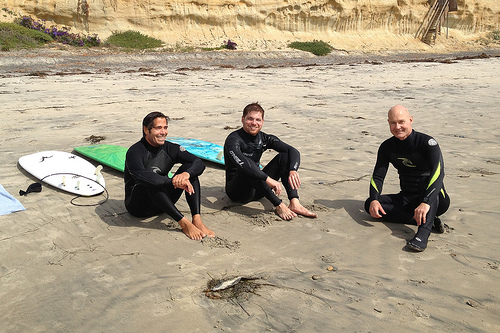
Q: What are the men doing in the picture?
A: Sitting.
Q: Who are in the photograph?
A: Men.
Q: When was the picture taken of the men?
A: Daytime.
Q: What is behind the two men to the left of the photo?
A: Surfboards.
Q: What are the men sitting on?
A: Sand.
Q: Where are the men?
A: Beach.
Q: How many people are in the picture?
A: Three.